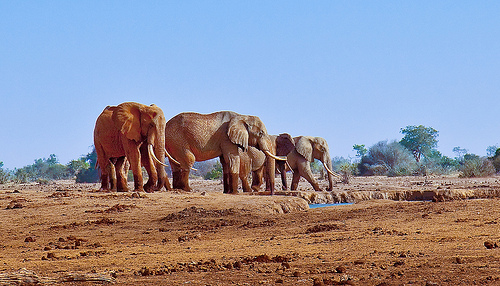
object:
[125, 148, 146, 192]
leg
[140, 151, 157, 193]
leg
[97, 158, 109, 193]
leg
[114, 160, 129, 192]
leg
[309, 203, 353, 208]
water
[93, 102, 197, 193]
elephant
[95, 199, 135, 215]
dirt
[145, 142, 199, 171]
tusk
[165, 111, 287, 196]
elephant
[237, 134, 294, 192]
elephant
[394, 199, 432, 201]
water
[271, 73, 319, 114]
cloud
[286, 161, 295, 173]
tusk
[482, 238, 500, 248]
dirt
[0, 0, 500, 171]
sky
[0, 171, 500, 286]
desert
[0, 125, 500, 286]
savanna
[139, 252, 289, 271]
dirt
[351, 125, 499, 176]
trees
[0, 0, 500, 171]
blue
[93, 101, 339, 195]
herd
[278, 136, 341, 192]
elephant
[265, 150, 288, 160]
tusk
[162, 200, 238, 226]
dirt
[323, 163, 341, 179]
tusk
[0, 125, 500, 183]
jungle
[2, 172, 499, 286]
ground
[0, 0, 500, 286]
background